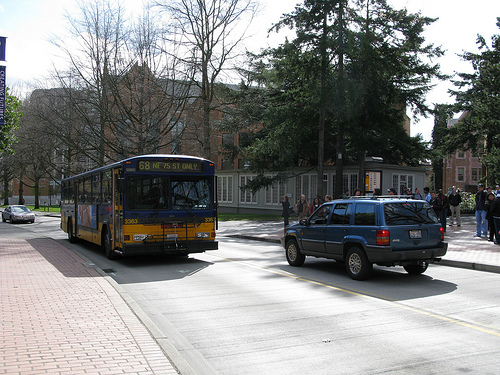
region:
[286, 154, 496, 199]
people having a chat on the road side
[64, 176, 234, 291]
a bus is on the road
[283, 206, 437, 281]
this car is also on the road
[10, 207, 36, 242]
another car is also on the road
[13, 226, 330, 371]
the road is clean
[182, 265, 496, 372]
the road is well carpeted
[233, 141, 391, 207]
buildings can be seen on the background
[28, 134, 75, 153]
trees are aslo on the background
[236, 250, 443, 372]
yellow markings on the road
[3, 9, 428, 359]
the weather looks sunny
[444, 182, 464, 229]
regular guy in beige trousers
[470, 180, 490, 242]
regular guy in light blue jeans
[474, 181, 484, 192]
regular guy in black cap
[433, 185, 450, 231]
dark-skinned black guy, no hair+red shirt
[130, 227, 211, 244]
rectangular horizontal headlights on bus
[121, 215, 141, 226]
blurry bus number, bus right front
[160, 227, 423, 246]
license plates are white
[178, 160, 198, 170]
the word 'only' in yellow electronic letters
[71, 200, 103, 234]
blue background sign with people on it on side of bus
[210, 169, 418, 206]
all windows of low grey building divided into three panes each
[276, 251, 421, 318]
a shadow is cast on the ground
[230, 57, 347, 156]
the tree is green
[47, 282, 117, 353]
the sidewalk is made of bricks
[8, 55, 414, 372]
it is sunny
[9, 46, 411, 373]
it is an outdoor scene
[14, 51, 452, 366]
it is a daytime scene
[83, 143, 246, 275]
the bus has number 65 at the front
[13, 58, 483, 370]
the road has vehicles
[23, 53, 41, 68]
the sky is covered by clouds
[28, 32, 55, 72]
the clouds are grey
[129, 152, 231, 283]
their is bus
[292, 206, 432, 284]
their is a car on the road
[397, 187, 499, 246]
people standing by the roadside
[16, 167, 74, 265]
a car is on coming in the road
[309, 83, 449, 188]
tress on the road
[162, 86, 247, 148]
their are buildings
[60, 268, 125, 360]
pavements on the road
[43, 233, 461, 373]
good roads on the image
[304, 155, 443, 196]
a group of people talking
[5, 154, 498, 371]
Street has two lanes.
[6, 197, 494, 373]
Driving surface has been paved.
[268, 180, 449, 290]
Vehicle on right is blue.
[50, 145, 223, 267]
Bus on left is blue and gold.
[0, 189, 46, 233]
Car is following behind bus.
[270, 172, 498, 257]
People are gathering on the sidewalk.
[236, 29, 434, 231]
Tree is tall and green.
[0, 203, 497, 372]
Asphalt is clean and dry.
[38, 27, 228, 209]
Tree branches are bare.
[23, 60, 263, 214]
Tall building in background